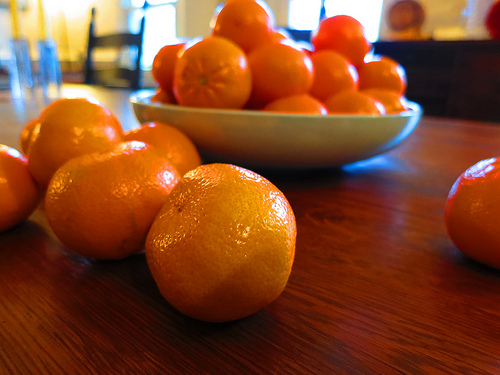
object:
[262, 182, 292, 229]
light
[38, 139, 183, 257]
orange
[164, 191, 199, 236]
orange middle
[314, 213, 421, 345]
table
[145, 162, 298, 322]
orange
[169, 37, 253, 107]
oranges